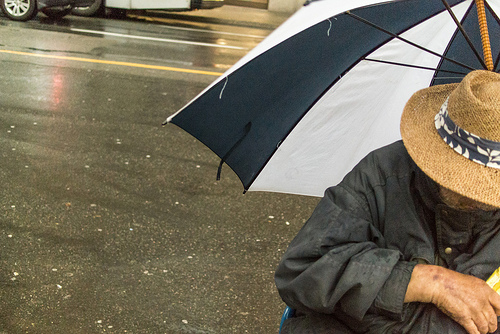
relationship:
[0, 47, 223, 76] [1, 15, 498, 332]
line in road